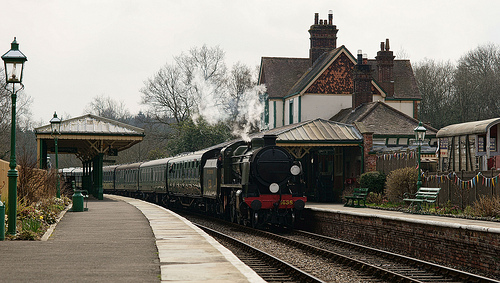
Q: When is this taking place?
A: Daytime.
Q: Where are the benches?
A: The sidewalk.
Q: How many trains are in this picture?
A: One.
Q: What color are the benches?
A: Green.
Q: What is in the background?
A: A train station.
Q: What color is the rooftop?
A: Brown.